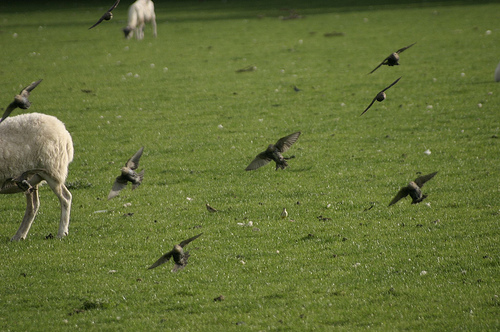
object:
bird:
[86, 0, 122, 31]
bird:
[107, 145, 148, 199]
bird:
[145, 228, 201, 278]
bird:
[245, 131, 303, 172]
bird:
[357, 76, 405, 117]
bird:
[387, 170, 439, 208]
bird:
[1, 75, 48, 122]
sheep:
[1, 111, 76, 243]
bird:
[367, 44, 414, 75]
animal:
[123, 0, 159, 40]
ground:
[3, 6, 497, 330]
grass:
[1, 3, 498, 331]